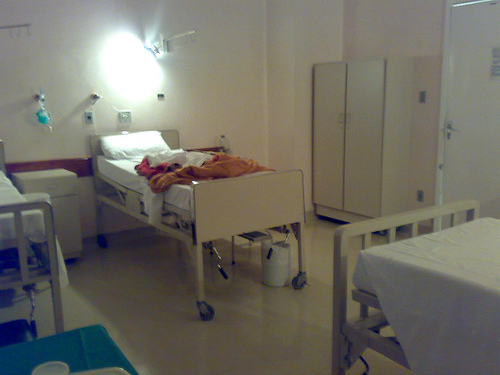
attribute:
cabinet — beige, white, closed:
[311, 59, 395, 232]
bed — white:
[76, 110, 317, 231]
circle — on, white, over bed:
[93, 34, 178, 110]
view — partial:
[91, 122, 265, 196]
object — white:
[259, 234, 320, 292]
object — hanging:
[33, 89, 55, 113]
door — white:
[414, 15, 498, 180]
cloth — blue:
[17, 319, 132, 372]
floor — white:
[94, 273, 256, 368]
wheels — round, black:
[191, 247, 345, 319]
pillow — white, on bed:
[98, 124, 179, 157]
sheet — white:
[154, 148, 207, 166]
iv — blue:
[29, 96, 61, 129]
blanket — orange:
[153, 154, 280, 187]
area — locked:
[329, 31, 403, 69]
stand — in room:
[82, 91, 115, 115]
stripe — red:
[7, 151, 112, 181]